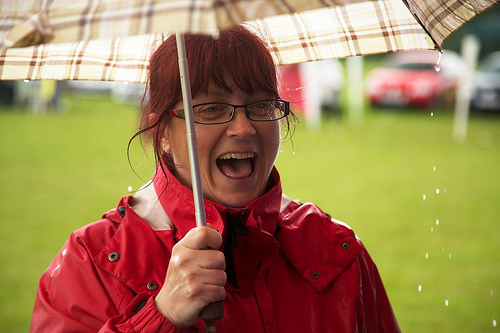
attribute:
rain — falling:
[417, 190, 427, 203]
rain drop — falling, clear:
[412, 109, 472, 267]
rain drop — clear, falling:
[389, 177, 474, 313]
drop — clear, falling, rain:
[433, 186, 440, 195]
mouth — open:
[212, 142, 261, 183]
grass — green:
[0, 94, 499, 332]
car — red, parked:
[363, 48, 459, 111]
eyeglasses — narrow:
[167, 95, 290, 127]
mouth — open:
[213, 146, 260, 183]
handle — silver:
[172, 33, 207, 226]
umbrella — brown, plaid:
[0, 0, 498, 84]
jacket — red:
[32, 21, 403, 329]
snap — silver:
[105, 249, 121, 264]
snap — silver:
[143, 278, 159, 294]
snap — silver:
[303, 265, 326, 281]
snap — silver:
[335, 235, 354, 248]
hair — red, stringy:
[122, 21, 301, 196]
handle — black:
[195, 297, 224, 330]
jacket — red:
[29, 150, 400, 330]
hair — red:
[119, 20, 295, 208]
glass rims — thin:
[164, 93, 292, 123]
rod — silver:
[171, 30, 208, 222]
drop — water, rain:
[426, 60, 449, 79]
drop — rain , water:
[414, 280, 425, 301]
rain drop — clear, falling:
[425, 106, 435, 120]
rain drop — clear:
[428, 186, 449, 201]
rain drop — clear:
[420, 251, 433, 264]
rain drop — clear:
[483, 312, 498, 333]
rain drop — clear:
[412, 155, 440, 180]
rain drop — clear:
[417, 219, 434, 234]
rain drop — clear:
[418, 245, 428, 268]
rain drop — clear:
[412, 275, 423, 298]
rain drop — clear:
[408, 284, 425, 294]